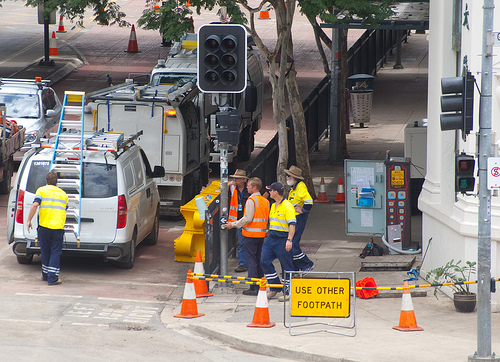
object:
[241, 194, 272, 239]
vest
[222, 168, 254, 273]
men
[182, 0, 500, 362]
sidewalk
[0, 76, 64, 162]
car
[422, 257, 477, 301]
plant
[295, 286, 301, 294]
black lettering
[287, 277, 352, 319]
banner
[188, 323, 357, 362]
curb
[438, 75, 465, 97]
traffic light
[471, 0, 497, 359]
pole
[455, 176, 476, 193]
traffic light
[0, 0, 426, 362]
ground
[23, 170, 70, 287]
guy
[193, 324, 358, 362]
edge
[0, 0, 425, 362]
road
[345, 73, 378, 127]
trash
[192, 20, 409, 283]
fencing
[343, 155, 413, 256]
box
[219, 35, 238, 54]
trafic light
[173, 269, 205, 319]
cone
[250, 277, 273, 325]
cone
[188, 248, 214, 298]
cone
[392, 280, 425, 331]
cone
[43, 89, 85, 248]
blue/yellow ladder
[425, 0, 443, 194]
wall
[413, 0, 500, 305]
building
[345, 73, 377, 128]
can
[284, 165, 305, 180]
hat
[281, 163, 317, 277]
guy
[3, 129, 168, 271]
truck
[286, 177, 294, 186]
beard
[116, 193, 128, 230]
tail lights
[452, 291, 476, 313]
planter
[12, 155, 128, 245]
van back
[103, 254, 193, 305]
part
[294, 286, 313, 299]
part